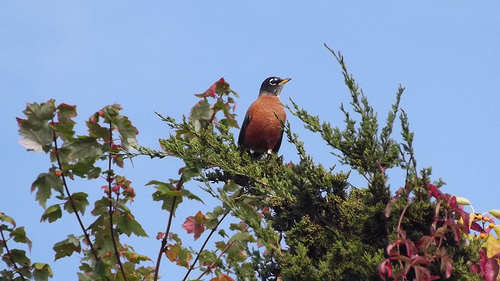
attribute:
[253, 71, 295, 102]
bird — sitting, robin, red, wild, looking, perched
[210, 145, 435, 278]
tree — evergreen, leafy, deciduous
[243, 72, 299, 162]
robin — sitting, perched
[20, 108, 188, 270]
tree — maple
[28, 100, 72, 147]
leaves — red, green, reddish, pink, yellow, pointy, evergreen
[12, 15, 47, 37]
sky — clear, blue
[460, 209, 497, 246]
sumac — turning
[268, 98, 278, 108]
breast — red, brown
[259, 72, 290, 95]
head — black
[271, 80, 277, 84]
eye — glossy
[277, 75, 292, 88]
beak — yellow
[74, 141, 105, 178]
leaf — green, brown, oak, red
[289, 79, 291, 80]
tip — yellow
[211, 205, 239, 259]
branches — brown, thin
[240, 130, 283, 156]
wings — black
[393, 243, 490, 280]
foliage — purple, spring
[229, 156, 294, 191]
branch — pine